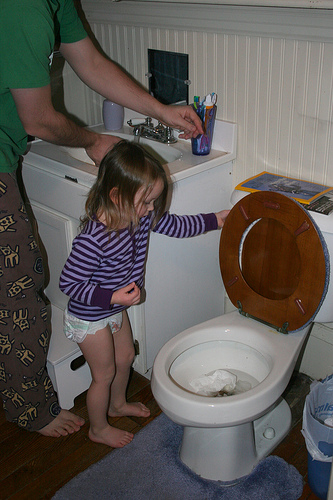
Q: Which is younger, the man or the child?
A: The child is younger than the man.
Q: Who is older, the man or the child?
A: The man is older than the child.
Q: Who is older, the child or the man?
A: The man is older than the child.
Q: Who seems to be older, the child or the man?
A: The man is older than the child.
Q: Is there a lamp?
A: No, there are no lamps.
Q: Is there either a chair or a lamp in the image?
A: No, there are no lamps or chairs.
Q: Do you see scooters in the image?
A: No, there are no scooters.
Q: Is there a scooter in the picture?
A: No, there are no scooters.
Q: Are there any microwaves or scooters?
A: No, there are no scooters or microwaves.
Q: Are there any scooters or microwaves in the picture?
A: No, there are no scooters or microwaves.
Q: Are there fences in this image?
A: No, there are no fences.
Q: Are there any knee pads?
A: No, there are no knee pads.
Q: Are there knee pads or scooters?
A: No, there are no knee pads or scooters.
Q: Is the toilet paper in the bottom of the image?
A: Yes, the toilet paper is in the bottom of the image.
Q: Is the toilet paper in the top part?
A: No, the toilet paper is in the bottom of the image.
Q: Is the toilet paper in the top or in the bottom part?
A: The toilet paper is in the bottom of the image.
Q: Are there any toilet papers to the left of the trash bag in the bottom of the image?
A: Yes, there is a toilet paper to the left of the trash bag.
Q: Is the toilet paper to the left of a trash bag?
A: Yes, the toilet paper is to the left of a trash bag.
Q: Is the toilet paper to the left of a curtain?
A: No, the toilet paper is to the left of a trash bag.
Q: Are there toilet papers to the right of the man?
A: Yes, there is a toilet paper to the right of the man.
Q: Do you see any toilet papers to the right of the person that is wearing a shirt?
A: Yes, there is a toilet paper to the right of the man.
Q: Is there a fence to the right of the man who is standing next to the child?
A: No, there is a toilet paper to the right of the man.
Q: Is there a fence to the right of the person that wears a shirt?
A: No, there is a toilet paper to the right of the man.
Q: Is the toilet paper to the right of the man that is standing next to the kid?
A: Yes, the toilet paper is to the right of the man.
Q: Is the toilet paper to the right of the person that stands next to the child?
A: Yes, the toilet paper is to the right of the man.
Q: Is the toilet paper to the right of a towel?
A: No, the toilet paper is to the right of the man.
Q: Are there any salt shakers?
A: No, there are no salt shakers.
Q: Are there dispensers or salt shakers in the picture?
A: No, there are no salt shakers or dispensers.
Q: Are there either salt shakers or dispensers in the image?
A: No, there are no salt shakers or dispensers.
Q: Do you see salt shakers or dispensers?
A: No, there are no salt shakers or dispensers.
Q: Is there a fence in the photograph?
A: No, there are no fences.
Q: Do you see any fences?
A: No, there are no fences.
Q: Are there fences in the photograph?
A: No, there are no fences.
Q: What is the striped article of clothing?
A: The clothing item is a shirt.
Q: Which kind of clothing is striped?
A: The clothing is a shirt.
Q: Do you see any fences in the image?
A: No, there are no fences.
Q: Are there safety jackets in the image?
A: No, there are no safety jackets.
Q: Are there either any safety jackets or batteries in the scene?
A: No, there are no safety jackets or batteries.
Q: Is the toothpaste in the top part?
A: Yes, the toothpaste is in the top of the image.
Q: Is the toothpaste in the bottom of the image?
A: No, the toothpaste is in the top of the image.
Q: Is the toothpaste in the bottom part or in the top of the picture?
A: The toothpaste is in the top of the image.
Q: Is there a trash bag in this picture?
A: Yes, there is a trash bag.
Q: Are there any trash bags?
A: Yes, there is a trash bag.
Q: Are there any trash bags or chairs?
A: Yes, there is a trash bag.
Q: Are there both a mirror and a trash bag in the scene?
A: Yes, there are both a trash bag and a mirror.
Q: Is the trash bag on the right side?
A: Yes, the trash bag is on the right of the image.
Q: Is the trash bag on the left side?
A: No, the trash bag is on the right of the image.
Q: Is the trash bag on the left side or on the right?
A: The trash bag is on the right of the image.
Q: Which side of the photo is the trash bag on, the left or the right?
A: The trash bag is on the right of the image.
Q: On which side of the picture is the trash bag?
A: The trash bag is on the right of the image.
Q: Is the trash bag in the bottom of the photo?
A: Yes, the trash bag is in the bottom of the image.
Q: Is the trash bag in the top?
A: No, the trash bag is in the bottom of the image.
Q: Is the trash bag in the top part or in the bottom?
A: The trash bag is in the bottom of the image.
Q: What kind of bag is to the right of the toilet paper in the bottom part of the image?
A: The bag is a trash bag.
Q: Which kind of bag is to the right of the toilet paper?
A: The bag is a trash bag.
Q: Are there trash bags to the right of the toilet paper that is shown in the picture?
A: Yes, there is a trash bag to the right of the toilet paper.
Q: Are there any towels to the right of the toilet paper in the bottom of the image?
A: No, there is a trash bag to the right of the toilet paper.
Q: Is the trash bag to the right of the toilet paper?
A: Yes, the trash bag is to the right of the toilet paper.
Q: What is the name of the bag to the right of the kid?
A: The bag is a trash bag.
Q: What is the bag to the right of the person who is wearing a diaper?
A: The bag is a trash bag.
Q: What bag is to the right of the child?
A: The bag is a trash bag.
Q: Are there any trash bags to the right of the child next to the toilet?
A: Yes, there is a trash bag to the right of the kid.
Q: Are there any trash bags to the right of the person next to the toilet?
A: Yes, there is a trash bag to the right of the kid.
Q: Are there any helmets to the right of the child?
A: No, there is a trash bag to the right of the child.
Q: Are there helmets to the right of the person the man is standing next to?
A: No, there is a trash bag to the right of the child.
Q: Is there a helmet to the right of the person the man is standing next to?
A: No, there is a trash bag to the right of the child.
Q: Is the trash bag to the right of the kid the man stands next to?
A: Yes, the trash bag is to the right of the child.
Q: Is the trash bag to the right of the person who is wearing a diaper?
A: Yes, the trash bag is to the right of the child.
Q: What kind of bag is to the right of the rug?
A: The bag is a trash bag.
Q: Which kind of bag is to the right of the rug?
A: The bag is a trash bag.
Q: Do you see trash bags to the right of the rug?
A: Yes, there is a trash bag to the right of the rug.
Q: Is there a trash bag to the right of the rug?
A: Yes, there is a trash bag to the right of the rug.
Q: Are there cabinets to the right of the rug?
A: No, there is a trash bag to the right of the rug.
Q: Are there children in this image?
A: Yes, there is a child.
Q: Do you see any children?
A: Yes, there is a child.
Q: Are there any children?
A: Yes, there is a child.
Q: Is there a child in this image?
A: Yes, there is a child.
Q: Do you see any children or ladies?
A: Yes, there is a child.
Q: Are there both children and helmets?
A: No, there is a child but no helmets.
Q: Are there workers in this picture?
A: No, there are no workers.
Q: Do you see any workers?
A: No, there are no workers.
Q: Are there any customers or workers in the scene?
A: No, there are no workers or customers.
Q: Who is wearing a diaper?
A: The child is wearing a diaper.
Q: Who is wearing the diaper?
A: The child is wearing a diaper.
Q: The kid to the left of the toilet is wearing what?
A: The kid is wearing a diaper.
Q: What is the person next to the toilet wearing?
A: The kid is wearing a diaper.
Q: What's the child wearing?
A: The kid is wearing a diaper.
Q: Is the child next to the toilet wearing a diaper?
A: Yes, the kid is wearing a diaper.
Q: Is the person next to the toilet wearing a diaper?
A: Yes, the kid is wearing a diaper.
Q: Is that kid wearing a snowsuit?
A: No, the kid is wearing a diaper.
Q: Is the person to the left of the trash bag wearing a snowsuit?
A: No, the kid is wearing a diaper.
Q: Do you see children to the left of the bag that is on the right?
A: Yes, there is a child to the left of the trash bag.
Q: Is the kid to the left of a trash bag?
A: Yes, the kid is to the left of a trash bag.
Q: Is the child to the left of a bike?
A: No, the child is to the left of a trash bag.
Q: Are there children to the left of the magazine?
A: Yes, there is a child to the left of the magazine.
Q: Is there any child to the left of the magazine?
A: Yes, there is a child to the left of the magazine.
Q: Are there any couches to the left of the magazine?
A: No, there is a child to the left of the magazine.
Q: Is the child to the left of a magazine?
A: Yes, the child is to the left of a magazine.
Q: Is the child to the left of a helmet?
A: No, the child is to the left of a magazine.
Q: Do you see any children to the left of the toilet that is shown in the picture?
A: Yes, there is a child to the left of the toilet.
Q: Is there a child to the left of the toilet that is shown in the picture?
A: Yes, there is a child to the left of the toilet.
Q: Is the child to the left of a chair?
A: No, the child is to the left of the toilet.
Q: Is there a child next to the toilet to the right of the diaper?
A: Yes, there is a child next to the toilet.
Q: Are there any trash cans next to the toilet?
A: No, there is a child next to the toilet.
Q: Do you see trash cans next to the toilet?
A: No, there is a child next to the toilet.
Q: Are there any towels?
A: No, there are no towels.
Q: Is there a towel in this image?
A: No, there are no towels.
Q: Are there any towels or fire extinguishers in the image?
A: No, there are no towels or fire extinguishers.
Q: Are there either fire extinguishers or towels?
A: No, there are no towels or fire extinguishers.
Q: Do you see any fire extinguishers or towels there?
A: No, there are no towels or fire extinguishers.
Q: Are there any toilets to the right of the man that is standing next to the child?
A: Yes, there is a toilet to the right of the man.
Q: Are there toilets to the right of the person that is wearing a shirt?
A: Yes, there is a toilet to the right of the man.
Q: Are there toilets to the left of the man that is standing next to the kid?
A: No, the toilet is to the right of the man.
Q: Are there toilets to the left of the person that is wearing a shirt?
A: No, the toilet is to the right of the man.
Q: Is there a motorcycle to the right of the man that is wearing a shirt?
A: No, there is a toilet to the right of the man.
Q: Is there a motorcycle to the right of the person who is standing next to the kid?
A: No, there is a toilet to the right of the man.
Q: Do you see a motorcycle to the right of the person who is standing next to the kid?
A: No, there is a toilet to the right of the man.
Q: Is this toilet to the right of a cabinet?
A: No, the toilet is to the right of the man.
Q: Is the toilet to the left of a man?
A: No, the toilet is to the right of a man.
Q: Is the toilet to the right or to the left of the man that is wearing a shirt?
A: The toilet is to the right of the man.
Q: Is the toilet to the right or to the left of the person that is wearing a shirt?
A: The toilet is to the right of the man.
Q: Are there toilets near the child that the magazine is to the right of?
A: Yes, there is a toilet near the child.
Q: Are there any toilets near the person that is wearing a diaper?
A: Yes, there is a toilet near the child.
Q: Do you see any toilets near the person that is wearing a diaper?
A: Yes, there is a toilet near the child.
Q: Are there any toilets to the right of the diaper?
A: Yes, there is a toilet to the right of the diaper.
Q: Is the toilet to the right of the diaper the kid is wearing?
A: Yes, the toilet is to the right of the diaper.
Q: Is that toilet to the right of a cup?
A: No, the toilet is to the right of the diaper.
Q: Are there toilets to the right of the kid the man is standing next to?
A: Yes, there is a toilet to the right of the kid.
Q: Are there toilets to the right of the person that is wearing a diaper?
A: Yes, there is a toilet to the right of the kid.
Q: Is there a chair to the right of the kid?
A: No, there is a toilet to the right of the kid.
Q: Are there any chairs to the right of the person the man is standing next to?
A: No, there is a toilet to the right of the kid.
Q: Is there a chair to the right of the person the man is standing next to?
A: No, there is a toilet to the right of the kid.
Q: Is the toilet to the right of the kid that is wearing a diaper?
A: Yes, the toilet is to the right of the kid.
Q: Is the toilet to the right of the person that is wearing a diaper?
A: Yes, the toilet is to the right of the kid.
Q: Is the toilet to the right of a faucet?
A: No, the toilet is to the right of the kid.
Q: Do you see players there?
A: No, there are no players.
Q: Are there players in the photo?
A: No, there are no players.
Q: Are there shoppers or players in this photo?
A: No, there are no players or shoppers.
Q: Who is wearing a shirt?
A: The man is wearing a shirt.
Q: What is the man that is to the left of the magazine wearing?
A: The man is wearing a shirt.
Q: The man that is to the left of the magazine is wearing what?
A: The man is wearing a shirt.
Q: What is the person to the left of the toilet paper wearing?
A: The man is wearing a shirt.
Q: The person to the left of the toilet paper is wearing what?
A: The man is wearing a shirt.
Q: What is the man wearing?
A: The man is wearing a shirt.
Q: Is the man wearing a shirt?
A: Yes, the man is wearing a shirt.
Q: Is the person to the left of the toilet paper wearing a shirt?
A: Yes, the man is wearing a shirt.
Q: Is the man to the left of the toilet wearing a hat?
A: No, the man is wearing a shirt.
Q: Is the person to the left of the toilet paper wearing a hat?
A: No, the man is wearing a shirt.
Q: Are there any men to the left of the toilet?
A: Yes, there is a man to the left of the toilet.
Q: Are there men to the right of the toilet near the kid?
A: No, the man is to the left of the toilet.